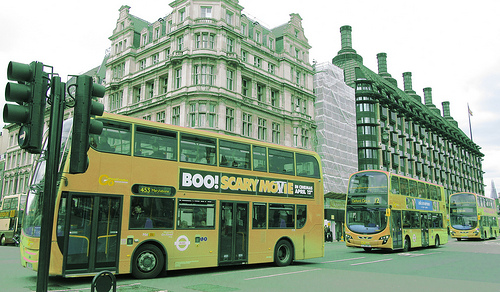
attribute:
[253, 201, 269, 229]
window — on lower level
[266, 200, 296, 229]
window — on lower level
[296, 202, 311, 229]
window — on lower level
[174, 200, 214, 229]
window — on lower level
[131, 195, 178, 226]
window — on lower level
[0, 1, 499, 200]
sky — cloudy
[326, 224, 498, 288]
street — where vehicles travel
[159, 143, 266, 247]
advertisement — Scary movie 5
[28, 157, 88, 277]
pole — black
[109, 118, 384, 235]
buses — double decker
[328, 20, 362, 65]
roof stack — five green 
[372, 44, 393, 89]
roof stack — five green 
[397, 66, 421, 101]
roof stack — five green 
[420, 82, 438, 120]
roof stack — five green 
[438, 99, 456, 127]
roof stack — five green 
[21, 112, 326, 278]
bus — double decker, yellow, in row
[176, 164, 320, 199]
billboard — Scary movie 5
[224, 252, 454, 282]
lines — white, broken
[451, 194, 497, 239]
bus — yellow, in row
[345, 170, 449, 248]
bus — yellow, in row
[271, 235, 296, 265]
tire — back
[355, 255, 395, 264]
line — white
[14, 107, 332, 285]
bus — lower level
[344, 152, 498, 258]
bus — upper level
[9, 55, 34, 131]
signal — traffic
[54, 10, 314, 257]
building — tall